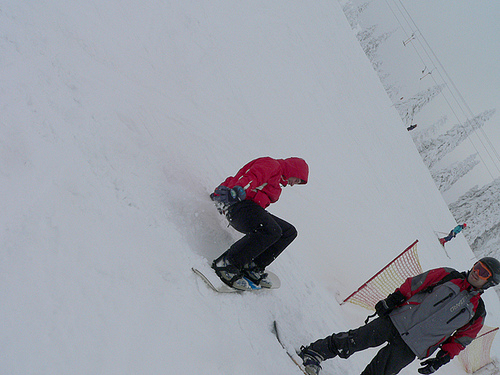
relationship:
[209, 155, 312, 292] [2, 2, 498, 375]
person in snow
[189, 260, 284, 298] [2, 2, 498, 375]
snowboard in snow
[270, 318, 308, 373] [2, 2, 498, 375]
snowboard in snow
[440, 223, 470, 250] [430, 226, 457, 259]
person on ski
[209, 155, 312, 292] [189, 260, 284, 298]
person falling on snowboard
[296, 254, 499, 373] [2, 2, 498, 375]
man standing in snow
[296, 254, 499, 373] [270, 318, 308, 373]
man standing on snowboard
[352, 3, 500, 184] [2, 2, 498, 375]
wires above snow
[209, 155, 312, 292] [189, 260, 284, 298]
person on a snowboard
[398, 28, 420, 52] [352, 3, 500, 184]
ski lift has wires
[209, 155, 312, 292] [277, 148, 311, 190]
person has head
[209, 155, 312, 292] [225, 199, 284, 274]
person has leg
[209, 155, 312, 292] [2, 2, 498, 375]
person falling on snow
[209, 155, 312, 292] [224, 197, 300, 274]
person wearing pants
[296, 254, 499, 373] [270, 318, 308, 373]
man on top of snowboard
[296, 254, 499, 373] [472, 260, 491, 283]
man wearing goggles